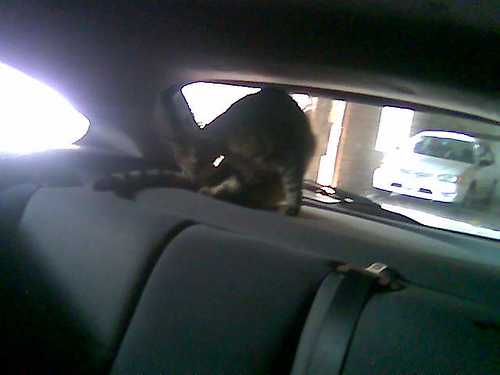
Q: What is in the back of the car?
A: Cat.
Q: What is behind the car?
A: White car.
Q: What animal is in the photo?
A: Cat.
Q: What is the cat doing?
A: Sitting in the back of a car.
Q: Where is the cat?
A: Towards the back windshield.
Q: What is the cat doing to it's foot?
A: Licking it.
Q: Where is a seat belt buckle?
A: On the back of the seat.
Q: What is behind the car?
A: A white car.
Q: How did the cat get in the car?
A: His owner let him in.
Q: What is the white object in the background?
A: A car.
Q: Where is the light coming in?
A: On the side window.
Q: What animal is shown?
A: Cat.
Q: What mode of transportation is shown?
A: Car.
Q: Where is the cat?
A: Back of car.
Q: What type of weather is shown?
A: Sunny.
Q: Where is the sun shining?
A: Left side of image.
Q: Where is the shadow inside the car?
A: Bottom half of the backseat.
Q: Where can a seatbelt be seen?
A: Bottom right side of image.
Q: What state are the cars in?
A: Parked.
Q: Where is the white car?
A: Behind the car the cat is in.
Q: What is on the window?
A: Windshield wiper.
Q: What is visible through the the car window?
A: There is a white car visible through the car window.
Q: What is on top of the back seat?
A: There is a cat on top of the back seat.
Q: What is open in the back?
A: There is an open garage in the back.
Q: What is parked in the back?
A: There is a white car parked in the back.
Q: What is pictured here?
A: The back seat of the car.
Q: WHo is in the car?
A: The cat is in the car.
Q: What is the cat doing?
A: The cat is cleaning itself.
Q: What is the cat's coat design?
A: The cat's coat is stripes.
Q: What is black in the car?
A: The seat belt is black in the car.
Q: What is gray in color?
A: The car seat.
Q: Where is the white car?
A: Parked in back.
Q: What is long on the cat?
A: The tail.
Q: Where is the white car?
A: Behind.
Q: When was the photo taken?
A: Daytime.